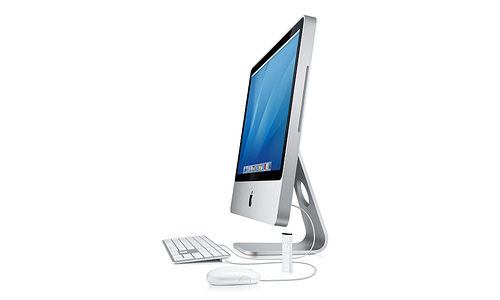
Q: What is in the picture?
A: A desktop.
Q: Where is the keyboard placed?
A: In Front of the desktop.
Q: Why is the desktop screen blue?
A: It is on.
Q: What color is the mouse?
A: White.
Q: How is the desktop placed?
A: It is upright.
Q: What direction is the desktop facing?
A: On the left.